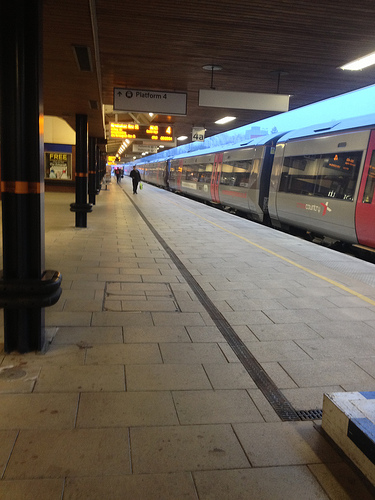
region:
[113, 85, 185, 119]
sign with platform 4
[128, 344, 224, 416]
sidewalk made of brick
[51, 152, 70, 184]
sign with free on it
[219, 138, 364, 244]
subway under ground station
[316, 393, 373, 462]
platform in subway station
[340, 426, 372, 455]
blue brick of platform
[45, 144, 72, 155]
blue paint above sign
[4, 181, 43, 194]
copper ring around pole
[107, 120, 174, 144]
sign with bus routes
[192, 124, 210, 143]
4a sign in black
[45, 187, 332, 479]
the ground is brick.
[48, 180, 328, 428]
The ground is grey.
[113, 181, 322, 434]
The drain is black.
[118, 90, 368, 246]
The subway is on a track.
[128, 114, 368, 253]
the subway is silver and red.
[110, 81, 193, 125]
the sign is white.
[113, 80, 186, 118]
Sign says platform 4.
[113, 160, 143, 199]
People waiting for subway.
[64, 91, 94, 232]
The poles are black.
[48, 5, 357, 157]
The ceiling is wooden.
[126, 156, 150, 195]
man walking in train terminal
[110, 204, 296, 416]
metal grate in flooring of train terminal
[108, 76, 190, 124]
black and white sign hanging from ceiling in terminal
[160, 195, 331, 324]
yellow line painted on tile of train terminal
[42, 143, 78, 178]
advertising banner in window of business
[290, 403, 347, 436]
drainage grate in flooring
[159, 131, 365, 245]
silver train cars with window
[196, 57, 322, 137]
blank white sign hanging from ceiling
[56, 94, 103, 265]
metal support beams in train terminal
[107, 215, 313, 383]
cement tile flooring in train terminal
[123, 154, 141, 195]
a man in the subway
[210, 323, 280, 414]
grate on the ground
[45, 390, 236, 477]
grey subway tiles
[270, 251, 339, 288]
yellow line on the ground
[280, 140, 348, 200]
window on a train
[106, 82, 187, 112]
sign with writing on it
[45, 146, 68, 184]
poster with writing on it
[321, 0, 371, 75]
light on ceiling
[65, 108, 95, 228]
post on ground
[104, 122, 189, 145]
sign with light writing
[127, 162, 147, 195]
person in black walking along train platform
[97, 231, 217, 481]
tan brick sidewalk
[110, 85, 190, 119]
black and white square platform sign hanging from ceiling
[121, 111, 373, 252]
long silver and coral train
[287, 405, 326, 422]
metal grate in ground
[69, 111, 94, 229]
black metal platform poles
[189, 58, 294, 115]
white sign hanging from train station ceiling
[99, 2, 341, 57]
wooden slat ceiling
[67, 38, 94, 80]
metal ceiling vent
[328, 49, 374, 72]
white rectangular ceiling light